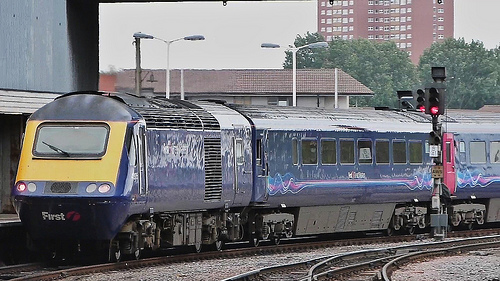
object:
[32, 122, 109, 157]
window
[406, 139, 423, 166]
window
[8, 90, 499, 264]
train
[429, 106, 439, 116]
light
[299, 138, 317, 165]
window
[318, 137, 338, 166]
window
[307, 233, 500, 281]
track